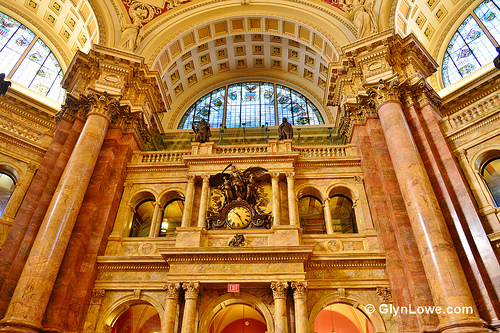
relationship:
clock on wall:
[222, 201, 250, 233] [109, 143, 408, 333]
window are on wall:
[176, 81, 322, 130] [109, 143, 408, 333]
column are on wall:
[350, 90, 497, 333] [109, 143, 408, 333]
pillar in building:
[10, 76, 158, 331] [6, 7, 478, 306]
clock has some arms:
[222, 201, 250, 233] [232, 209, 245, 224]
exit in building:
[228, 284, 240, 293] [6, 7, 478, 306]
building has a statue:
[0, 0, 500, 333] [196, 119, 292, 144]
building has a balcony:
[0, 0, 500, 333] [127, 194, 365, 250]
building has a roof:
[6, 7, 478, 306] [17, 3, 476, 83]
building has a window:
[6, 7, 478, 306] [165, 78, 320, 131]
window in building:
[165, 78, 320, 131] [6, 7, 478, 306]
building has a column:
[6, 7, 478, 306] [360, 79, 499, 302]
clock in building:
[222, 201, 250, 233] [6, 7, 478, 306]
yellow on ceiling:
[149, 12, 385, 89] [140, 25, 391, 125]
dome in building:
[17, 3, 476, 83] [6, 7, 478, 306]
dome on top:
[17, 3, 476, 83] [128, 3, 358, 28]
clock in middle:
[222, 201, 250, 233] [125, 133, 370, 331]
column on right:
[360, 79, 499, 302] [355, 72, 461, 283]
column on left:
[360, 79, 499, 302] [19, 100, 127, 315]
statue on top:
[196, 119, 292, 144] [128, 3, 358, 28]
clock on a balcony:
[222, 201, 250, 233] [127, 194, 365, 250]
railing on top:
[132, 137, 356, 157] [128, 3, 358, 28]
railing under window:
[132, 137, 356, 157] [165, 78, 320, 131]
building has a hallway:
[6, 7, 478, 306] [218, 311, 264, 332]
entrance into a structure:
[222, 320, 268, 332] [6, 7, 478, 306]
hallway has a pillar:
[218, 311, 264, 332] [10, 76, 158, 331]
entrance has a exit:
[222, 320, 268, 332] [229, 279, 241, 294]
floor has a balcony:
[125, 202, 371, 254] [127, 194, 365, 250]